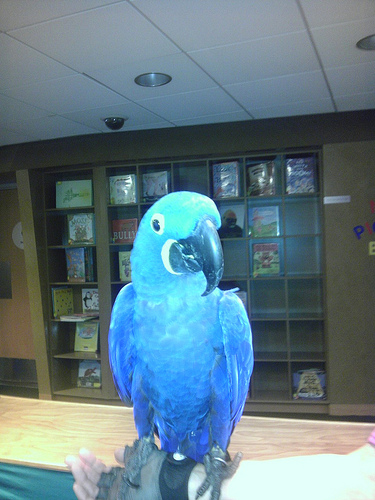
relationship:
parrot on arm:
[118, 203, 238, 415] [61, 441, 375, 492]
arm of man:
[61, 441, 375, 492] [283, 409, 374, 485]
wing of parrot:
[217, 285, 255, 424] [118, 203, 238, 415]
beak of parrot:
[187, 228, 234, 299] [118, 203, 238, 415]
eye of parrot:
[150, 213, 162, 235] [118, 203, 238, 415]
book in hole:
[54, 179, 97, 204] [42, 173, 100, 209]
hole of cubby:
[42, 173, 100, 209] [37, 179, 314, 398]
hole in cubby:
[42, 173, 100, 209] [37, 179, 314, 398]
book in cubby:
[54, 179, 97, 204] [37, 179, 314, 398]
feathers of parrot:
[138, 289, 198, 372] [108, 191, 254, 500]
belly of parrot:
[135, 327, 204, 409] [108, 191, 254, 500]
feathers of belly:
[138, 289, 198, 372] [135, 327, 204, 409]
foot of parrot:
[198, 440, 231, 496] [108, 191, 254, 500]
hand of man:
[66, 426, 162, 498] [283, 409, 374, 485]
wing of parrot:
[221, 287, 272, 427] [108, 191, 254, 500]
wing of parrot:
[217, 285, 255, 424] [108, 191, 254, 500]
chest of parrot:
[145, 307, 201, 340] [108, 191, 254, 500]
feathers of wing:
[238, 340, 262, 392] [221, 287, 272, 427]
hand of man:
[66, 426, 162, 498] [65, 440, 374, 498]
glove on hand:
[111, 433, 196, 500] [66, 426, 162, 498]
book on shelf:
[111, 220, 145, 248] [50, 186, 327, 389]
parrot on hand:
[118, 203, 238, 415] [66, 426, 162, 498]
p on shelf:
[350, 220, 362, 245] [50, 186, 327, 389]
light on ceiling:
[132, 67, 173, 99] [10, 10, 351, 135]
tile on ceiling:
[16, 24, 320, 147] [10, 10, 351, 135]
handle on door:
[1, 259, 13, 309] [1, 187, 31, 401]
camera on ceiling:
[101, 113, 129, 129] [10, 10, 351, 135]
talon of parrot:
[197, 448, 241, 499] [118, 203, 238, 415]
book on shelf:
[54, 179, 97, 204] [50, 186, 327, 389]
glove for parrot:
[111, 433, 196, 500] [108, 191, 254, 500]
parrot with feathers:
[118, 203, 238, 415] [138, 289, 198, 372]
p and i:
[350, 220, 362, 245] [362, 224, 375, 237]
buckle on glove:
[166, 448, 202, 471] [111, 433, 196, 500]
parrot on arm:
[108, 191, 254, 500] [61, 441, 375, 492]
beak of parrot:
[187, 228, 234, 299] [108, 191, 254, 500]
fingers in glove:
[56, 446, 98, 498] [111, 433, 196, 500]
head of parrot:
[126, 191, 246, 300] [108, 191, 254, 500]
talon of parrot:
[211, 448, 241, 500] [108, 191, 254, 500]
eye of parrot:
[150, 213, 162, 235] [108, 191, 254, 500]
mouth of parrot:
[170, 254, 211, 277] [108, 191, 254, 500]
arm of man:
[61, 441, 375, 492] [65, 440, 374, 498]